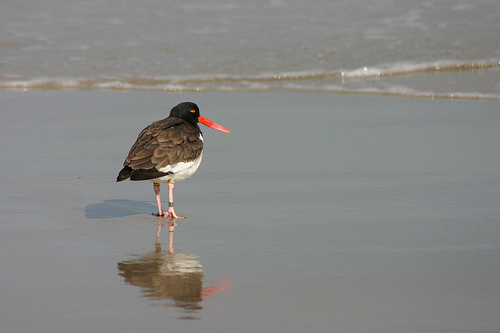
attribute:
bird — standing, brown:
[115, 100, 232, 223]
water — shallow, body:
[0, 2, 499, 104]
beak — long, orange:
[196, 113, 233, 138]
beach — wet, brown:
[2, 88, 500, 333]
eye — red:
[189, 106, 198, 115]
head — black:
[169, 100, 200, 127]